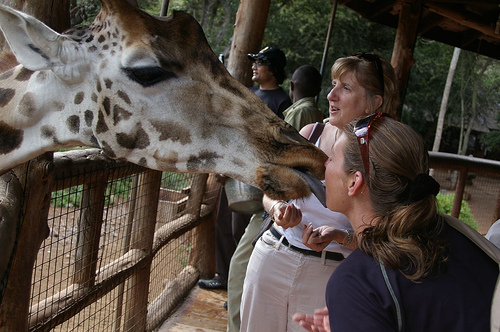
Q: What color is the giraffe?
A: Light brown.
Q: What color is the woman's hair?
A: Sunglasses.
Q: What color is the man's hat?
A: Navy.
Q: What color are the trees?
A: Green.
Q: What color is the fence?
A: Light wood.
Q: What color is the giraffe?
A: Brown and white.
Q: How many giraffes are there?
A: One.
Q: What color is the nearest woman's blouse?
A: Blue.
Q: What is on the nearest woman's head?
A: Sunglasses.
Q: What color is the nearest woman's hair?
A: Brown.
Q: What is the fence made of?
A: Wood and wire.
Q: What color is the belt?
A: Black.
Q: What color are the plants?
A: Green.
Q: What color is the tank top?
A: White.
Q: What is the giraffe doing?
A: Licking the woman.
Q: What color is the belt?
A: Black.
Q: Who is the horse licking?
A: The woman in the blue shirt.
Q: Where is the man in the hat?
A: Behind the women.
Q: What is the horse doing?
A: Licking the woman's face.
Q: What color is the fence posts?
A: Brown.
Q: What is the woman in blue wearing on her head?
A: Sunglasses.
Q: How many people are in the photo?
A: 4.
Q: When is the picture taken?
A: During the daytime.